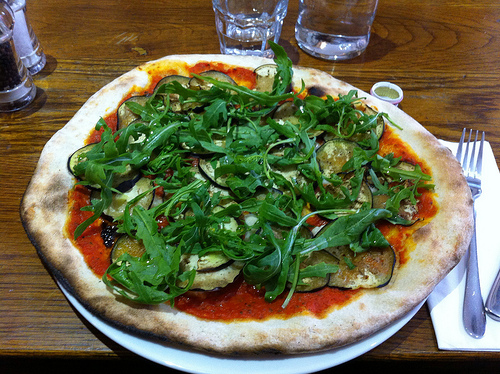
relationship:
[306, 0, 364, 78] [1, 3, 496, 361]
glass on table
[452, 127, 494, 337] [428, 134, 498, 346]
fork on napkin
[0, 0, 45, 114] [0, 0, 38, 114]
pepper shaker by pepper shaker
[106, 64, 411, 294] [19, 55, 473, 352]
vegetable on pizza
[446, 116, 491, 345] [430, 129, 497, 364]
fork on napkin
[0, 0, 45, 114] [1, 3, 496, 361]
pepper shaker on table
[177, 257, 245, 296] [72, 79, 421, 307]
eggplant on pizza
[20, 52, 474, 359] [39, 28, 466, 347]
crust on pizza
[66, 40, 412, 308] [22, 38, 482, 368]
vegetable on pizza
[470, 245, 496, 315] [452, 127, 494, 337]
handle on fork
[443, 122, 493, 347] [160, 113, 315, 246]
fork next to pizza